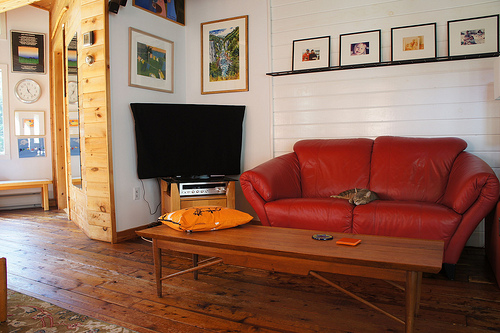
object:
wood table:
[132, 223, 446, 333]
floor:
[0, 207, 500, 333]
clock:
[13, 76, 43, 105]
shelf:
[264, 50, 500, 78]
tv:
[129, 103, 246, 180]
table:
[160, 175, 241, 217]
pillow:
[156, 205, 255, 234]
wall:
[184, 0, 499, 248]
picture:
[446, 14, 500, 58]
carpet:
[0, 287, 141, 333]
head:
[352, 187, 372, 207]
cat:
[329, 186, 381, 205]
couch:
[237, 134, 500, 266]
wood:
[0, 257, 8, 325]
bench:
[0, 178, 54, 211]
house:
[0, 0, 500, 333]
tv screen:
[129, 102, 246, 179]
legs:
[404, 270, 419, 333]